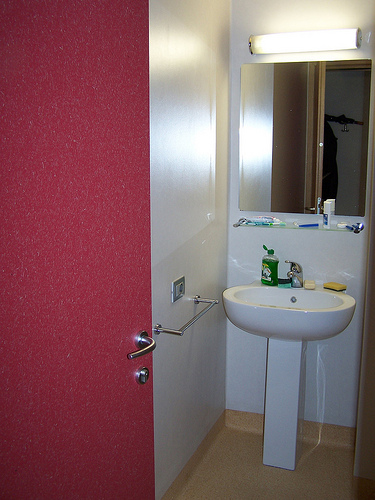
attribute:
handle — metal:
[118, 325, 160, 362]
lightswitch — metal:
[172, 276, 185, 302]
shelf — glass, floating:
[233, 220, 364, 231]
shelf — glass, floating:
[232, 221, 356, 233]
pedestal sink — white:
[220, 282, 356, 470]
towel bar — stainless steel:
[153, 294, 218, 335]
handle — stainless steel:
[123, 326, 161, 361]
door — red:
[6, 1, 157, 491]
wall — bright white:
[149, 0, 229, 498]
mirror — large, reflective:
[238, 64, 369, 225]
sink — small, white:
[222, 280, 355, 471]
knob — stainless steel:
[126, 327, 158, 360]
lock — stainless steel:
[132, 363, 149, 386]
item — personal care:
[319, 194, 338, 230]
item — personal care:
[291, 216, 322, 231]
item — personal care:
[231, 216, 248, 227]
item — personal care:
[242, 219, 274, 229]